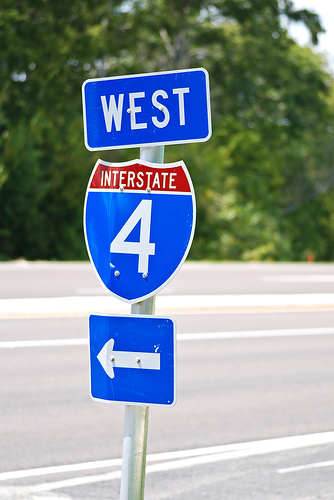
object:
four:
[107, 198, 155, 272]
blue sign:
[81, 66, 212, 152]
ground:
[0, 260, 334, 500]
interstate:
[0, 261, 334, 500]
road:
[0, 261, 334, 500]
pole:
[118, 400, 144, 500]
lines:
[0, 430, 334, 494]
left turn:
[87, 314, 177, 408]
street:
[3, 260, 331, 498]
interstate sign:
[81, 158, 197, 305]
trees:
[0, 0, 334, 269]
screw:
[159, 106, 163, 111]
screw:
[147, 188, 150, 193]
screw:
[120, 187, 124, 191]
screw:
[142, 273, 148, 279]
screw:
[114, 270, 120, 277]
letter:
[101, 84, 189, 132]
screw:
[111, 357, 115, 362]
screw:
[137, 359, 140, 364]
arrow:
[96, 337, 160, 379]